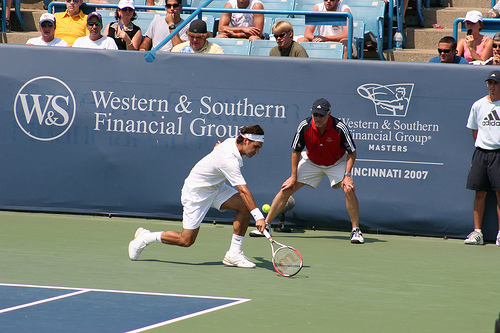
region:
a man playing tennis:
[118, 117, 311, 287]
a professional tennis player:
[112, 113, 314, 286]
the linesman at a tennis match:
[266, 87, 368, 242]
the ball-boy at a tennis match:
[463, 70, 498, 247]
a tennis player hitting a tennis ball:
[118, 104, 320, 289]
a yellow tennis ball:
[256, 197, 272, 214]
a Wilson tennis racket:
[263, 231, 305, 278]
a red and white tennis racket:
[262, 228, 306, 280]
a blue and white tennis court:
[1, 276, 248, 327]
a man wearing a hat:
[302, 93, 335, 135]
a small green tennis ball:
[260, 201, 270, 212]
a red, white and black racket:
[260, 225, 305, 275]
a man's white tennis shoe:
[222, 251, 256, 268]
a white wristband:
[249, 207, 264, 221]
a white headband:
[234, 129, 268, 141]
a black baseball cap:
[309, 98, 336, 117]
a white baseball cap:
[459, 11, 485, 23]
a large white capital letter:
[90, 88, 114, 111]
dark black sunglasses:
[432, 46, 453, 55]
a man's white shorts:
[291, 148, 346, 186]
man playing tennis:
[117, 113, 312, 272]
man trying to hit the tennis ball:
[103, 116, 315, 280]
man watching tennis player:
[252, 90, 373, 245]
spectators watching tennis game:
[30, 0, 331, 46]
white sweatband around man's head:
[227, 118, 275, 161]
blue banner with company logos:
[6, 78, 490, 203]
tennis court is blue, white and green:
[28, 215, 103, 320]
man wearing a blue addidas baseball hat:
[294, 91, 340, 124]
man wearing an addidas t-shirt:
[460, 84, 497, 154]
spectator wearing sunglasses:
[427, 35, 471, 72]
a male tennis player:
[127, 124, 303, 279]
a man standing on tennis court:
[251, 96, 366, 241]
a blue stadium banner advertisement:
[2, 45, 499, 240]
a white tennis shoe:
[128, 227, 147, 261]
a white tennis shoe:
[221, 247, 254, 267]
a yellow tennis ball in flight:
[263, 201, 271, 214]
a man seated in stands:
[266, 21, 307, 56]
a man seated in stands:
[76, 11, 114, 46]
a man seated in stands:
[25, 13, 65, 48]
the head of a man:
[232, 118, 270, 160]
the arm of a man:
[220, 161, 262, 215]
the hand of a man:
[251, 211, 273, 235]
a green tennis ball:
[257, 200, 274, 216]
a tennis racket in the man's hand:
[259, 222, 307, 279]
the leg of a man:
[144, 190, 209, 250]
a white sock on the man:
[143, 228, 169, 247]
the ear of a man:
[240, 134, 250, 147]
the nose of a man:
[251, 145, 262, 155]